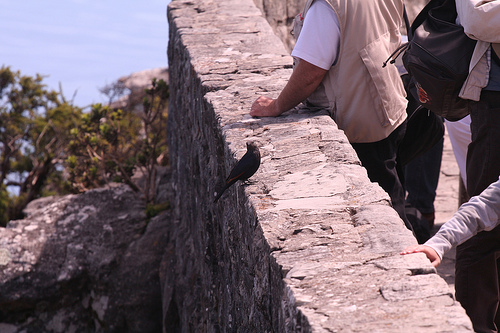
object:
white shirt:
[290, 3, 339, 71]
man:
[249, 1, 418, 147]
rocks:
[369, 252, 436, 272]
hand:
[249, 92, 280, 121]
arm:
[250, 6, 342, 118]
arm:
[400, 180, 499, 265]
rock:
[215, 57, 229, 63]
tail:
[213, 184, 229, 204]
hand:
[399, 240, 442, 267]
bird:
[213, 138, 260, 198]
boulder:
[0, 159, 164, 302]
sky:
[0, 0, 169, 21]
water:
[0, 8, 163, 81]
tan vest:
[324, 11, 411, 142]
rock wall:
[166, 1, 476, 331]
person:
[399, 175, 499, 266]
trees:
[0, 66, 77, 218]